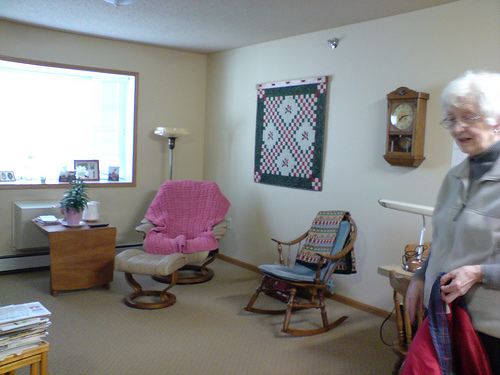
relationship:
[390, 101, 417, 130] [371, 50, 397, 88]
clock on wall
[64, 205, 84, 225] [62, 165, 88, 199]
vase has flowers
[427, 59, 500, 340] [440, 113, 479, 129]
lady wearing spectacles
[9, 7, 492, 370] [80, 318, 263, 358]
room has a floor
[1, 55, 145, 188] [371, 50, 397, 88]
window on wall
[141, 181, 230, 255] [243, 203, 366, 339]
blanket spread on chair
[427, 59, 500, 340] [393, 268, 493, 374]
woman carrying a jacket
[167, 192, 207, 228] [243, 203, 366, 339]
blanket on back of chair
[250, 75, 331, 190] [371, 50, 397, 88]
painting hanging on wall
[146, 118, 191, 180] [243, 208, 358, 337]
lamp behind chair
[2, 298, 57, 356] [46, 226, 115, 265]
papers on table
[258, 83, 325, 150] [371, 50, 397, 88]
painting on wall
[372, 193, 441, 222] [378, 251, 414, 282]
lamp on desk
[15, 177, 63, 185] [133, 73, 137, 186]
windowsill has a frame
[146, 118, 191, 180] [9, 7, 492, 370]
lamp in corner of living room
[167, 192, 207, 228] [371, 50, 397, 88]
blanket hanging on wall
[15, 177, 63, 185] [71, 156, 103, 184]
windowsill has a picture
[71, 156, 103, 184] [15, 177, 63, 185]
picture on windowsill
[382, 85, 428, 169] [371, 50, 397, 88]
clock on wall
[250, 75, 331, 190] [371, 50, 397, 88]
painting on wall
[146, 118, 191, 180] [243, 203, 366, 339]
pole lamp behind chair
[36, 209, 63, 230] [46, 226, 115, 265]
mail on table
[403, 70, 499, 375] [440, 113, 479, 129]
lady has eyeglasses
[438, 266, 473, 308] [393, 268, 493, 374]
hand holding jacket